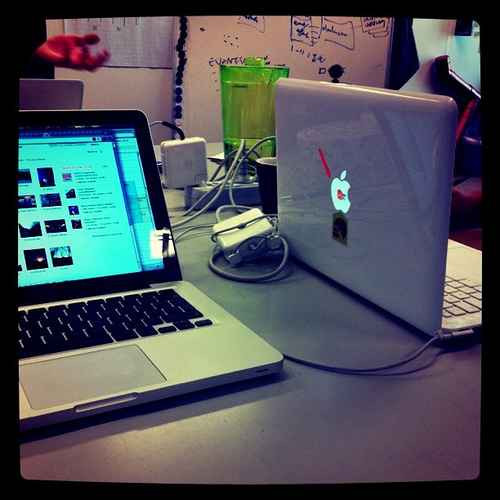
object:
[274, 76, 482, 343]
computer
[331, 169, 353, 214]
logo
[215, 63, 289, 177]
cup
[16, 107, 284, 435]
computer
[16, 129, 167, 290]
screen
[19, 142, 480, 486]
table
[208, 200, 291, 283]
cord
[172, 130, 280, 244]
wires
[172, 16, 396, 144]
board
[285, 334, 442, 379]
wire